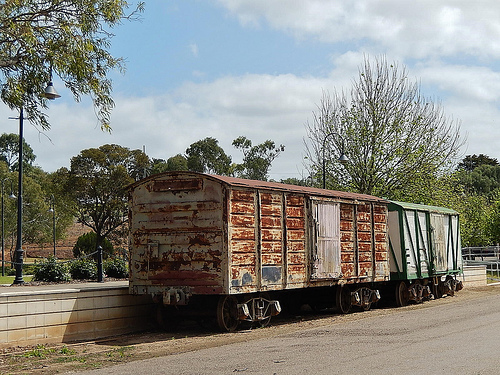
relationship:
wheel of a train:
[215, 292, 246, 333] [114, 178, 466, 334]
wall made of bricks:
[1, 291, 154, 349] [40, 306, 104, 332]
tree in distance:
[54, 146, 132, 277] [149, 40, 221, 81]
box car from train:
[120, 177, 388, 334] [114, 178, 466, 334]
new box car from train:
[385, 201, 465, 307] [114, 178, 466, 334]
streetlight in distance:
[10, 32, 34, 291] [149, 40, 221, 81]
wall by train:
[1, 291, 154, 349] [114, 178, 466, 334]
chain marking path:
[281, 328, 437, 338] [464, 290, 489, 374]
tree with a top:
[54, 146, 132, 277] [80, 146, 132, 166]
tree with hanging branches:
[54, 146, 132, 277] [431, 127, 463, 179]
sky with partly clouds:
[259, 27, 327, 77] [206, 74, 301, 130]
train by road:
[114, 178, 466, 334] [5, 337, 494, 373]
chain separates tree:
[281, 328, 437, 338] [54, 146, 132, 277]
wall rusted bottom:
[1, 291, 154, 349] [5, 331, 115, 343]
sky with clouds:
[259, 27, 327, 77] [206, 74, 301, 130]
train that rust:
[114, 178, 466, 334] [235, 207, 252, 255]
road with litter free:
[5, 337, 494, 373] [377, 329, 449, 367]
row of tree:
[56, 130, 283, 174] [54, 146, 132, 277]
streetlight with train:
[10, 32, 34, 291] [114, 178, 466, 334]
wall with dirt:
[1, 291, 154, 349] [244, 339, 278, 363]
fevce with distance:
[26, 236, 73, 258] [149, 40, 221, 81]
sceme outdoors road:
[1, 3, 499, 372] [5, 337, 494, 373]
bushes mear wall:
[37, 245, 127, 288] [1, 291, 154, 349]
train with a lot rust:
[114, 178, 466, 334] [235, 207, 252, 255]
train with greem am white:
[114, 178, 466, 334] [402, 208, 454, 272]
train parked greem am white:
[114, 178, 466, 334] [402, 208, 454, 272]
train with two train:
[114, 178, 466, 334] [123, 172, 467, 333]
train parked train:
[114, 178, 466, 334] [123, 172, 467, 333]